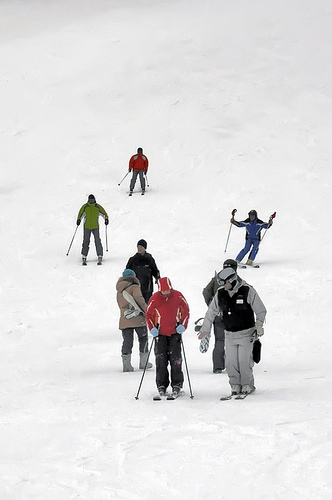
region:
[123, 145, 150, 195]
person skiing in white snow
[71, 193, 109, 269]
person skiing in white snow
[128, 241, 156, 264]
person skiing in white snow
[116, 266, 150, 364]
person skiing in white snow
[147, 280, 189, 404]
person skiing in white snow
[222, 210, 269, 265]
person skiing in white snow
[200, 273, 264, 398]
person skiing in white snow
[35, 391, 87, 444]
white snow on hill side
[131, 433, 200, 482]
white snow on hill side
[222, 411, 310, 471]
white snow on hill side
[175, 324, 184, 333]
gloves that are blue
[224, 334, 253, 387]
grey pants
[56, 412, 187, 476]
the snow is white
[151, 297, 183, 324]
a red sweater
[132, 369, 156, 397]
a ski pole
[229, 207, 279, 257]
a person skiing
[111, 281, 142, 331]
a brown and grey coat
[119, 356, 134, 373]
grey boots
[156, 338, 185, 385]
black pants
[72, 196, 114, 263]
a person skiing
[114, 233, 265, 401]
people at bottom of slope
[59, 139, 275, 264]
skiers nearing bottom of slope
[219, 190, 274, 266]
skier raising poles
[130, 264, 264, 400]
one skier talking to another skier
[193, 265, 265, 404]
skier making motion with hand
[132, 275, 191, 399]
skier looking down with poles at sides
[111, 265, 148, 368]
woman walking on snow in boots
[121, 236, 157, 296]
man in dark outfit looking to side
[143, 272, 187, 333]
hooded red and white jacket with white stripes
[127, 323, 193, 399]
light blue gloves at end of poles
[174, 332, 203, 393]
a person holding a ski pole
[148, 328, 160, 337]
blue gloves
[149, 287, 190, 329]
a person wearing a red jacket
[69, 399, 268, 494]
the snow is white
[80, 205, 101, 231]
a green a grey jacket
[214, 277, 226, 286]
snow goggles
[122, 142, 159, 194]
persone skiing down hill side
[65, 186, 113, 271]
persone skiing down hill side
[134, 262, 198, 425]
persone skiing down hill side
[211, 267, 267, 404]
persone skiing down hill side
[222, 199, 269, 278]
persone skiing down hill side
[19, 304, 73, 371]
white snow on hill side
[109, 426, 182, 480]
white snow on hill side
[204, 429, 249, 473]
white snow on hill side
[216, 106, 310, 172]
white snow on hill side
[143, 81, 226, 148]
white snow on hill side